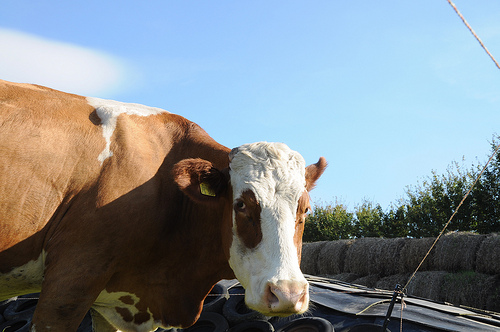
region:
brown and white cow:
[13, 75, 322, 315]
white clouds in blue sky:
[387, 35, 423, 73]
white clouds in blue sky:
[374, 123, 411, 142]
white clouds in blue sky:
[18, 16, 80, 44]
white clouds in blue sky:
[52, 21, 114, 69]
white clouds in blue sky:
[255, 48, 322, 93]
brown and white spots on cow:
[102, 281, 146, 329]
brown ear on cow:
[161, 139, 261, 239]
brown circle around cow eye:
[227, 177, 283, 271]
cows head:
[178, 119, 361, 328]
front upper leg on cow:
[15, 202, 160, 324]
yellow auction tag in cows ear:
[192, 168, 230, 201]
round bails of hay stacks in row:
[329, 205, 495, 289]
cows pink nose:
[241, 252, 338, 330]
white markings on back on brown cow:
[50, 74, 221, 229]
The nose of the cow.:
[265, 275, 309, 311]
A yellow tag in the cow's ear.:
[201, 180, 218, 197]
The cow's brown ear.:
[168, 154, 230, 211]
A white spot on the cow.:
[86, 92, 165, 164]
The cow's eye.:
[233, 196, 248, 215]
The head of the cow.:
[172, 142, 327, 317]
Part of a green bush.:
[426, 204, 449, 221]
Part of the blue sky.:
[351, 92, 396, 141]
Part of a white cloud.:
[30, 43, 62, 73]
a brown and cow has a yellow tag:
[5, 84, 499, 327]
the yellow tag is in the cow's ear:
[169, 150, 234, 207]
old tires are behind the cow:
[8, 280, 325, 330]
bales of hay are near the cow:
[301, 230, 499, 308]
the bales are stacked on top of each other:
[309, 230, 498, 314]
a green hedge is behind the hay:
[309, 142, 499, 242]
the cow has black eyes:
[233, 190, 315, 219]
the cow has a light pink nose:
[263, 274, 311, 321]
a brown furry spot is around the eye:
[228, 178, 265, 252]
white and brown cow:
[12, 76, 335, 325]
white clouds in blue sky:
[380, 67, 449, 124]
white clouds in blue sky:
[72, 32, 97, 52]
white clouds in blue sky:
[329, 57, 425, 141]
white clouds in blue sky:
[269, 6, 332, 66]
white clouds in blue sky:
[391, 36, 435, 64]